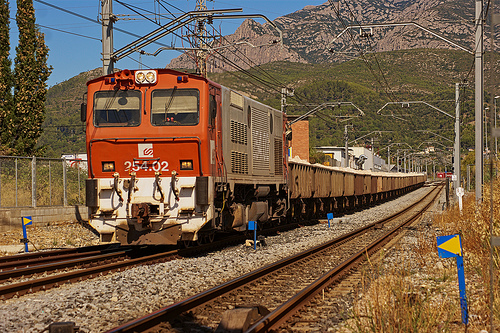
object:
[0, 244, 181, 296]
tracks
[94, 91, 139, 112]
blinds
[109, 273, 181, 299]
rocks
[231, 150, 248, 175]
vents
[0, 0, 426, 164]
cables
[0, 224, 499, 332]
ground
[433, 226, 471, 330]
sign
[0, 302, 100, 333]
gravel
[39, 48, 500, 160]
grass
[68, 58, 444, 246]
train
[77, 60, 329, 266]
train is orange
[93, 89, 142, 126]
windows of train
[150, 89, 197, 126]
windows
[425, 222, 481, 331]
yellow sign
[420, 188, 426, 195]
between the tracks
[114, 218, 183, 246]
rust colored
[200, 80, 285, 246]
side of train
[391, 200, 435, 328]
part of a ground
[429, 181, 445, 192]
edge of a rail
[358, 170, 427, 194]
edge of a train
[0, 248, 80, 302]
edge of a rail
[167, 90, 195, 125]
part of a window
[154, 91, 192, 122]
part of a window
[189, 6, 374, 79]
rocky mountain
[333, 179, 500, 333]
brown bushes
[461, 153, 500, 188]
grass and weeds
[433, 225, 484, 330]
yellow flag sign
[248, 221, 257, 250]
blue flag sign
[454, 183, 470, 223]
white paddle sign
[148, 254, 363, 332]
empty railroad track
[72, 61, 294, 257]
train engine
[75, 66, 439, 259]
powered train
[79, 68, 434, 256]
long train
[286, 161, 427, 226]
brown box cars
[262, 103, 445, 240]
tracks side by side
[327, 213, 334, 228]
short signal pole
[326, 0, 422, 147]
wires and supports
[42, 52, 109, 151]
steep mountain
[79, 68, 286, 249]
engine car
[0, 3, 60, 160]
skinny trees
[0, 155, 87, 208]
chainlink fence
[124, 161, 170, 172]
white number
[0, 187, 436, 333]
two parallel sets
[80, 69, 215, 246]
front of the train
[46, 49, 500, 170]
hillside is covered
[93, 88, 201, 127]
two windows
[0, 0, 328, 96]
bright blue sky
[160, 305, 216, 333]
shadow on the tracks